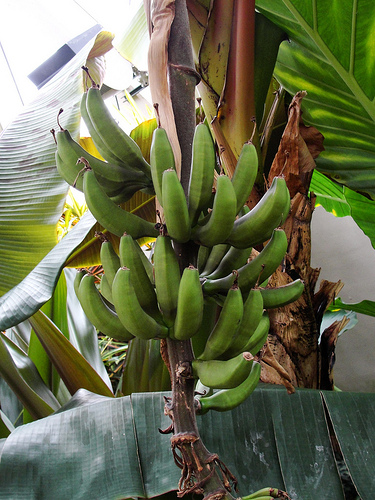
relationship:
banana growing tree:
[150, 102, 177, 208] [66, 0, 310, 498]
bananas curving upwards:
[70, 232, 209, 345] [110, 235, 234, 332]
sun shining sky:
[3, 6, 92, 82] [3, 6, 37, 33]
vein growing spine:
[332, 0, 360, 76] [202, 92, 244, 172]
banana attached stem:
[191, 351, 254, 390] [167, 342, 202, 464]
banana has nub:
[111, 265, 168, 340] [116, 229, 132, 240]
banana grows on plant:
[112, 265, 167, 342] [258, 3, 374, 198]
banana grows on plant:
[174, 264, 204, 343] [258, 3, 374, 198]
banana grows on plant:
[153, 209, 181, 327] [258, 3, 374, 198]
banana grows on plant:
[189, 350, 253, 387] [258, 3, 374, 198]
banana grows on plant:
[236, 176, 283, 244] [258, 3, 374, 198]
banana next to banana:
[152, 230, 182, 326] [174, 261, 206, 342]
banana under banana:
[158, 170, 197, 247] [148, 122, 181, 212]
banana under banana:
[158, 170, 197, 247] [186, 116, 213, 218]